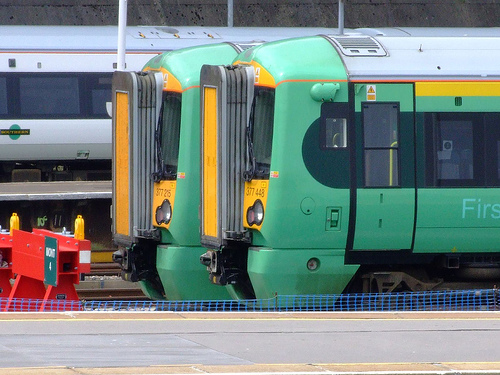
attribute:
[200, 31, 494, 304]
train — yellow, green, aqua colored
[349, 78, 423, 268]
door — green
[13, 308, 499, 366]
road — empty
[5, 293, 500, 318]
netting — blue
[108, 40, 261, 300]
train — yellow, transit, green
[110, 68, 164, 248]
door — gray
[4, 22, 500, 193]
train — grey, white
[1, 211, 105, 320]
device — red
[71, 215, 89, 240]
light — yellow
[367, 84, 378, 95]
sticker — yellow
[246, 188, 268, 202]
numbers — black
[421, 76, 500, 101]
stripe — yellow